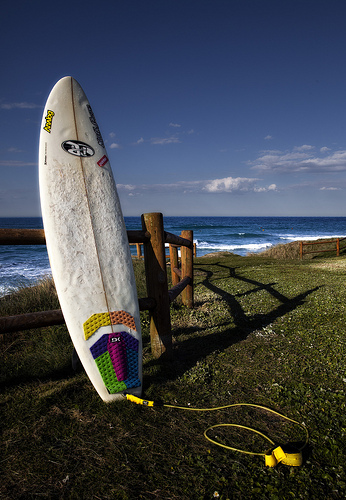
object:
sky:
[1, 1, 344, 215]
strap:
[125, 390, 311, 467]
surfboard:
[39, 74, 144, 404]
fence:
[5, 211, 196, 359]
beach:
[1, 236, 346, 367]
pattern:
[59, 138, 96, 158]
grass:
[1, 256, 342, 495]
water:
[227, 215, 260, 234]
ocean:
[0, 215, 345, 294]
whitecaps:
[204, 242, 213, 248]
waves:
[248, 241, 262, 248]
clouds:
[3, 101, 345, 198]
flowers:
[59, 487, 77, 500]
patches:
[83, 305, 138, 341]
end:
[69, 309, 146, 402]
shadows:
[142, 255, 326, 383]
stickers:
[42, 100, 57, 137]